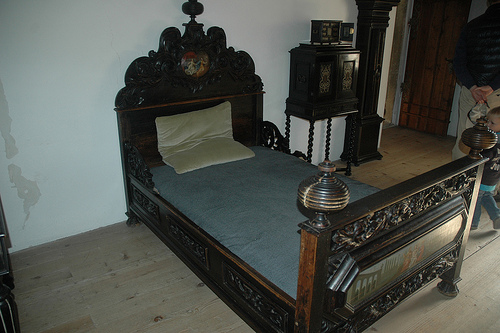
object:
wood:
[262, 288, 279, 307]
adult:
[453, 0, 498, 159]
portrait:
[181, 49, 211, 78]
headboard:
[112, 0, 265, 170]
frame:
[117, 2, 499, 333]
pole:
[295, 159, 352, 230]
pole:
[460, 118, 498, 158]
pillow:
[155, 100, 255, 174]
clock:
[339, 0, 400, 168]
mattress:
[149, 144, 412, 300]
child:
[470, 105, 499, 231]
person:
[445, 1, 500, 162]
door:
[397, 0, 471, 139]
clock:
[181, 50, 212, 78]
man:
[446, 2, 500, 162]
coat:
[449, 7, 500, 92]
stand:
[284, 42, 360, 175]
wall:
[2, 0, 356, 255]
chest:
[285, 41, 360, 122]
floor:
[0, 218, 499, 332]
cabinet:
[282, 19, 362, 120]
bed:
[115, 0, 497, 332]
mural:
[326, 166, 480, 327]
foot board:
[293, 117, 499, 333]